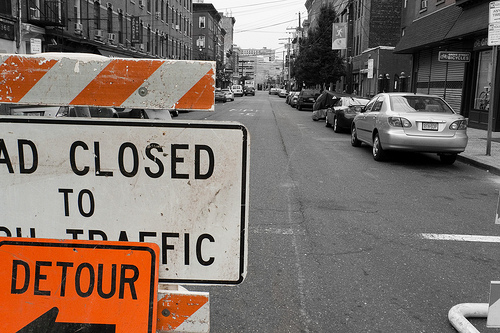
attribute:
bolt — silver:
[138, 86, 148, 96]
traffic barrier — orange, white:
[0, 48, 249, 328]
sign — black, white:
[3, 112, 290, 284]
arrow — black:
[15, 306, 117, 331]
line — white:
[422, 227, 496, 245]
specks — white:
[3, 56, 135, 111]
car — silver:
[349, 87, 469, 162]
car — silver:
[344, 87, 474, 167]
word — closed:
[66, 140, 217, 181]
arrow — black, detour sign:
[6, 302, 123, 332]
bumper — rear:
[381, 131, 468, 156]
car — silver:
[348, 91, 470, 166]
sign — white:
[0, 113, 249, 287]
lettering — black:
[0, 136, 213, 261]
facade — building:
[408, 7, 498, 142]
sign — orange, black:
[0, 238, 158, 330]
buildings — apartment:
[0, 0, 235, 85]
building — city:
[0, 1, 196, 100]